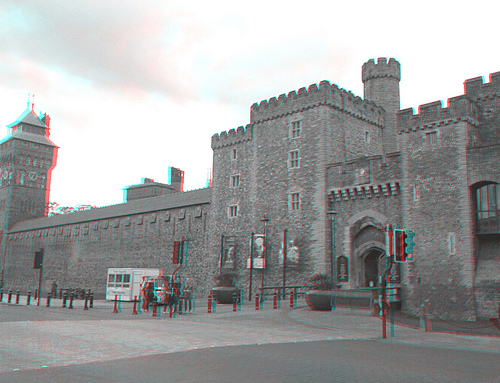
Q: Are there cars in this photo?
A: No, there are no cars.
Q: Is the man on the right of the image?
A: Yes, the man is on the right of the image.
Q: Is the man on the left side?
A: No, the man is on the right of the image.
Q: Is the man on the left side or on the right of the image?
A: The man is on the right of the image.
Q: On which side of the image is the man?
A: The man is on the right of the image.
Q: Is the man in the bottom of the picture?
A: Yes, the man is in the bottom of the image.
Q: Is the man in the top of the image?
A: No, the man is in the bottom of the image.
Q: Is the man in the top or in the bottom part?
A: The man is in the bottom of the image.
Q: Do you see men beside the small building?
A: Yes, there is a man beside the building.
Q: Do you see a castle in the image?
A: Yes, there is a castle.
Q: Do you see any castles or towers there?
A: Yes, there is a castle.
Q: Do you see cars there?
A: No, there are no cars.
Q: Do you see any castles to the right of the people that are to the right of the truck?
A: Yes, there is a castle to the right of the people.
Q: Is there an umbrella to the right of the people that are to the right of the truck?
A: No, there is a castle to the right of the people.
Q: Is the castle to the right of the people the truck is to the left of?
A: Yes, the castle is to the right of the people.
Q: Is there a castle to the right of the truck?
A: Yes, there is a castle to the right of the truck.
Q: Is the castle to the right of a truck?
A: Yes, the castle is to the right of a truck.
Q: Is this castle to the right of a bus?
A: No, the castle is to the right of a truck.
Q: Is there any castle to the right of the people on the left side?
A: Yes, there is a castle to the right of the people.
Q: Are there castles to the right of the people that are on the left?
A: Yes, there is a castle to the right of the people.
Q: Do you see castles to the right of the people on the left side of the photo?
A: Yes, there is a castle to the right of the people.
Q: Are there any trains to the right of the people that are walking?
A: No, there is a castle to the right of the people.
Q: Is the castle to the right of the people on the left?
A: Yes, the castle is to the right of the people.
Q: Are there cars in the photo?
A: No, there are no cars.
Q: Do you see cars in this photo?
A: No, there are no cars.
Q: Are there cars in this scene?
A: No, there are no cars.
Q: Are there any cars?
A: No, there are no cars.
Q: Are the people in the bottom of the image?
A: Yes, the people are in the bottom of the image.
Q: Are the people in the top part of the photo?
A: No, the people are in the bottom of the image.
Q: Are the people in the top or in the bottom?
A: The people are in the bottom of the image.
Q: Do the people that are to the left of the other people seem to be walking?
A: Yes, the people are walking.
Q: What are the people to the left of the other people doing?
A: The people are walking.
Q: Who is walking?
A: The people are walking.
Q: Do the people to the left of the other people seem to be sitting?
A: No, the people are walking.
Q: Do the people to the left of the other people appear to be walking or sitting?
A: The people are walking.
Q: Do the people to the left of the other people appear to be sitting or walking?
A: The people are walking.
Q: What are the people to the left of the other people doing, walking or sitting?
A: The people are walking.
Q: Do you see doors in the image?
A: Yes, there is a door.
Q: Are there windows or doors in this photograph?
A: Yes, there is a door.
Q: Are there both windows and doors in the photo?
A: Yes, there are both a door and windows.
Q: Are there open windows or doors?
A: Yes, there is an open door.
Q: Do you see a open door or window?
A: Yes, there is an open door.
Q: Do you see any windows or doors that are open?
A: Yes, the door is open.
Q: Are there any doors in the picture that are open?
A: Yes, there is an open door.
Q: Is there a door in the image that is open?
A: Yes, there is a door that is open.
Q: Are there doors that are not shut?
A: Yes, there is a open door.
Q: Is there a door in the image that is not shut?
A: Yes, there is a open door.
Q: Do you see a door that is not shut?
A: Yes, there is a open door.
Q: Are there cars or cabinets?
A: No, there are no cars or cabinets.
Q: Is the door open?
A: Yes, the door is open.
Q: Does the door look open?
A: Yes, the door is open.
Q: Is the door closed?
A: No, the door is open.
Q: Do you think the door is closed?
A: No, the door is open.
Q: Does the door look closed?
A: No, the door is open.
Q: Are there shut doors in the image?
A: No, there is a door but it is open.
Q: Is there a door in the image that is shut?
A: No, there is a door but it is open.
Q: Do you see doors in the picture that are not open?
A: No, there is a door but it is open.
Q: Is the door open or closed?
A: The door is open.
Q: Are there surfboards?
A: No, there are no surfboards.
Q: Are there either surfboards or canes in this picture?
A: No, there are no surfboards or canes.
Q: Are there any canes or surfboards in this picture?
A: No, there are no surfboards or canes.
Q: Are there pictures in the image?
A: No, there are no pictures.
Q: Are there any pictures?
A: No, there are no pictures.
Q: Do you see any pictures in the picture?
A: No, there are no pictures.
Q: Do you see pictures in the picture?
A: No, there are no pictures.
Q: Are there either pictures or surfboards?
A: No, there are no pictures or surfboards.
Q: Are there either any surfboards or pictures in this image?
A: No, there are no pictures or surfboards.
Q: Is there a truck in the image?
A: Yes, there is a truck.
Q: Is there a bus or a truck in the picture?
A: Yes, there is a truck.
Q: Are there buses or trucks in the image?
A: Yes, there is a truck.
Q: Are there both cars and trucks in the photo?
A: No, there is a truck but no cars.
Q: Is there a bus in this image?
A: No, there are no buses.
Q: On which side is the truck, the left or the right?
A: The truck is on the left of the image.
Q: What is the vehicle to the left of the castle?
A: The vehicle is a truck.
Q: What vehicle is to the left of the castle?
A: The vehicle is a truck.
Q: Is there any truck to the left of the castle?
A: Yes, there is a truck to the left of the castle.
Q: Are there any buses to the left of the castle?
A: No, there is a truck to the left of the castle.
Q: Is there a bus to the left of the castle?
A: No, there is a truck to the left of the castle.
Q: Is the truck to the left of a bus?
A: No, the truck is to the left of a castle.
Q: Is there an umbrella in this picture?
A: No, there are no umbrellas.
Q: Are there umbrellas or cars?
A: No, there are no umbrellas or cars.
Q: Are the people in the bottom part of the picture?
A: Yes, the people are in the bottom of the image.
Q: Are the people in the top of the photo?
A: No, the people are in the bottom of the image.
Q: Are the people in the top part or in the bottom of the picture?
A: The people are in the bottom of the image.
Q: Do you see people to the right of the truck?
A: Yes, there are people to the right of the truck.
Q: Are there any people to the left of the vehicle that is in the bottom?
A: No, the people are to the right of the truck.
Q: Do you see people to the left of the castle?
A: Yes, there are people to the left of the castle.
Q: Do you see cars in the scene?
A: No, there are no cars.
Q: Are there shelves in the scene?
A: No, there are no shelves.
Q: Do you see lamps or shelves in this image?
A: No, there are no shelves or lamps.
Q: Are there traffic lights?
A: Yes, there is a traffic light.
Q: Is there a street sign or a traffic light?
A: Yes, there is a traffic light.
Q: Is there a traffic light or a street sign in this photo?
A: Yes, there is a traffic light.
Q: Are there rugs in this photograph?
A: No, there are no rugs.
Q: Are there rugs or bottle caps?
A: No, there are no rugs or bottle caps.